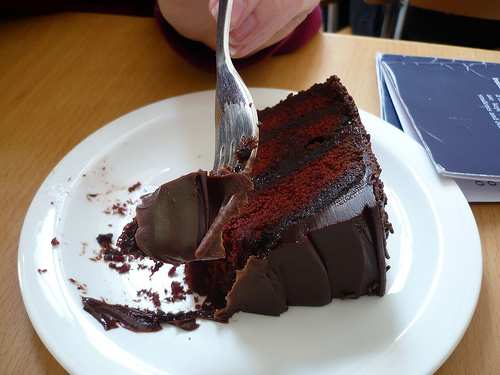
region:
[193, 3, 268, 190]
a large silver fork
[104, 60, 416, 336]
a piece of cake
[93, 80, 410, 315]
red velvet cake with chocolate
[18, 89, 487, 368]
cake on a white plate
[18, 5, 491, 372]
person eating a cake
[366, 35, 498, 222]
an old book on a table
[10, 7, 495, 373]
large piece of chocolate cake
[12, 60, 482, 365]
chocolate frosting on a cake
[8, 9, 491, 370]
cake on a table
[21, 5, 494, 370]
cake cut with a fork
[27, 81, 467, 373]
A piece of cake on a white plate.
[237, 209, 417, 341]
Chocolate frosting on a cake.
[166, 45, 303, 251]
Fork digging into a chocolate cake.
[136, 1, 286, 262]
Hand holding a fork.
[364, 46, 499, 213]
A book next to a plate.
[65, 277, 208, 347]
Chocolate frosting smudge on the plate.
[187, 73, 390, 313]
Three layers on the slice of chocolate cake.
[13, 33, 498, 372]
The table is made of wood.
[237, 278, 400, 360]
A shadow by the slice of cake.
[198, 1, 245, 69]
The handle of the fork.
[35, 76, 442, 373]
white plate holding a piece of cake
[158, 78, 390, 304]
one piece of chocolate cake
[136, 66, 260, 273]
silver fork picking up cake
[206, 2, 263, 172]
woman's hand holding fork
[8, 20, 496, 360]
smooth wooden table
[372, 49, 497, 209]
two blue books on a table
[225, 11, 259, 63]
long unpolished finger nails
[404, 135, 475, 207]
corner of blue book on the plate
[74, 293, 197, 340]
brown chocolate frosting smeared on plate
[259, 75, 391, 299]
chocolate cake with three layers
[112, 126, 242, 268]
A PIECE OF CHOCOLATE CAKE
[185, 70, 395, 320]
A SLICE OF CHOCOLATE CAKE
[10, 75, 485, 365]
A PLATE OF CHOCOLATE CAKE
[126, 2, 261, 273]
A FORK WITH CAKE ON IT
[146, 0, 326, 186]
A PICTURE OF A HAND HOLDING A FORK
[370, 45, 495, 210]
A BOOKLET NEXT TO THE PLATE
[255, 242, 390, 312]
CHOCOLATE FROSTING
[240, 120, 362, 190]
FROSTING BETWEEN THE CAKE SLICES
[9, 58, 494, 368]
A PLATE OF CAKE ON A TABLE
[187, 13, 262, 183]
A PICTURE OF A FORK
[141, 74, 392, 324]
a piece of chocolate cake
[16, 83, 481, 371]
a round white plate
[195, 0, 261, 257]
a metal fork with cake on it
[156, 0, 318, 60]
a person's hand holding a fork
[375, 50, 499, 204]
a couple of blue booklets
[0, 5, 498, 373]
a wooden table top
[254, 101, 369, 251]
lines of frosting on the cake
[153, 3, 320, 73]
the sleeve of a colored shirt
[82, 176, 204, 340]
smeared frosting on the plate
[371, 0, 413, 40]
a metal pole behind the table